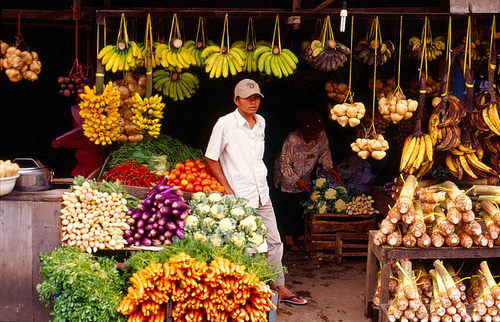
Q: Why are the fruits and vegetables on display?
A: They are for sale.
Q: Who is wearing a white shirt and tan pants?
A: The man in the baseball cap.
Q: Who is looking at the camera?
A: The man in the white shirt.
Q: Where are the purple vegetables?
A: On a stand above the carrots.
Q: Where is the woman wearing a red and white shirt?
A: Behind the man with the white shirt.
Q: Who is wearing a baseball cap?
A: The man wearing khakis.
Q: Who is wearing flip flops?
A: The man looking at the camera.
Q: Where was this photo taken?
A: At a produce stand.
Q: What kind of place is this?
A: Market place.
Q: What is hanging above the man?
A: Bananas.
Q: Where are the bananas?
A: Hanging along the shop.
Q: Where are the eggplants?
A: On a shelf in the front of the store.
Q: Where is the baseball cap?
A: On the head of the man in the white shirt.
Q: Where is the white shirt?
A: On the man wearing a baseball cap.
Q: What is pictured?
A: Produce stand.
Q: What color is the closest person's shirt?
A: White.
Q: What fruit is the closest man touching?
A: Tomato.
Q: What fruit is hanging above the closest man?
A: Banana.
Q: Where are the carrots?
A: Left of walkway.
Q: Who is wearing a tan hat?
A: Closest man.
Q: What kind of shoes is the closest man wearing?
A: Flip flops.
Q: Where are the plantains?
A: Far right.